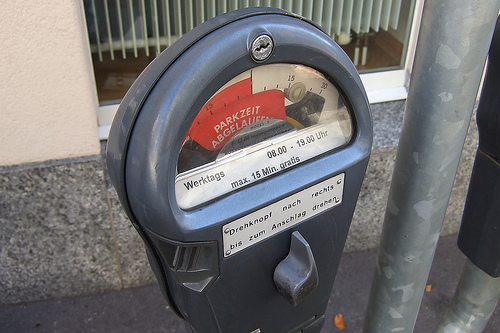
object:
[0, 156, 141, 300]
wall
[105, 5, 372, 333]
meter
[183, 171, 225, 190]
word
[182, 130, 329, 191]
label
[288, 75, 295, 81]
numbers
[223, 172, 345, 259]
label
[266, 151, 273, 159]
numbers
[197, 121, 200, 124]
line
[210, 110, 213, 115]
line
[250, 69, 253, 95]
line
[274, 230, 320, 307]
knob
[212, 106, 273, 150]
lettering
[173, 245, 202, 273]
coin slot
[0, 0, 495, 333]
building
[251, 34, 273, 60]
keyhole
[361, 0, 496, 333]
pole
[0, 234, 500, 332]
sidewalk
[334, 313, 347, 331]
leaf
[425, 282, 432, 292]
leaf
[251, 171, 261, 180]
numbers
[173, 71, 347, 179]
background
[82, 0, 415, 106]
window